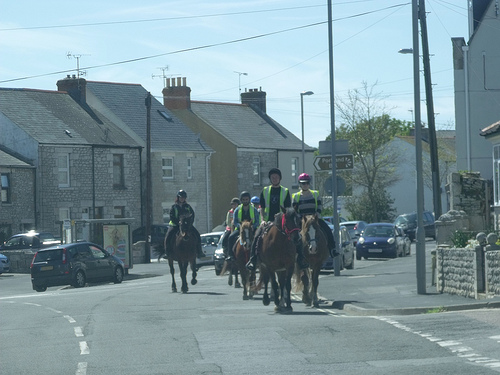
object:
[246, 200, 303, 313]
horse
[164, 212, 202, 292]
horse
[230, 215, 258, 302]
horse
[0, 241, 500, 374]
road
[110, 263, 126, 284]
wheel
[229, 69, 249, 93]
antenna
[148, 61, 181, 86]
antenna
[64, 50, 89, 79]
antenna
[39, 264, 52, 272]
license plate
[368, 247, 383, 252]
license plate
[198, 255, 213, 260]
license plate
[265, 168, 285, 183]
helmet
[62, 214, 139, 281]
shelter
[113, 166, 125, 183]
building window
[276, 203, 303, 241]
horsehead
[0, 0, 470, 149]
sky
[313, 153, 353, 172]
signs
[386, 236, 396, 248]
headlight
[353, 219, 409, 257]
car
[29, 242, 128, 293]
car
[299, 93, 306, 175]
pole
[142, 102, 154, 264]
pole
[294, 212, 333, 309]
horse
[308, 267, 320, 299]
leg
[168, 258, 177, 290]
leg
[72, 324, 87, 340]
line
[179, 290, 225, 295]
shadow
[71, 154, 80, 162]
stone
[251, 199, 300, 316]
horse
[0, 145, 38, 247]
houses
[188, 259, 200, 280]
leg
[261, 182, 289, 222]
vest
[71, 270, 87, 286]
wheel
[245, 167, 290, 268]
man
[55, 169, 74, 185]
window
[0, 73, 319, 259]
building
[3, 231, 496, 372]
street